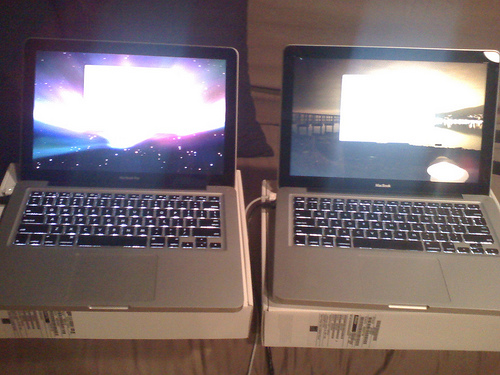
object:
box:
[260, 177, 500, 352]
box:
[0, 160, 255, 340]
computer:
[0, 35, 246, 314]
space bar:
[349, 236, 424, 251]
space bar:
[73, 232, 150, 249]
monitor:
[289, 55, 490, 183]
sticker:
[301, 312, 383, 350]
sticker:
[1, 308, 80, 338]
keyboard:
[292, 195, 499, 257]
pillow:
[0, 0, 274, 160]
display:
[29, 52, 226, 174]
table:
[0, 92, 499, 374]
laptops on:
[3, 252, 238, 304]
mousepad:
[74, 249, 159, 300]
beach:
[289, 139, 481, 184]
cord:
[245, 301, 260, 373]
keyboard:
[11, 190, 227, 252]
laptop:
[271, 42, 498, 315]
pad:
[377, 250, 452, 305]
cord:
[243, 191, 277, 217]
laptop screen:
[31, 50, 229, 175]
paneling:
[131, 340, 203, 373]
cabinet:
[0, 348, 499, 374]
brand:
[374, 181, 391, 188]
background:
[0, 0, 499, 187]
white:
[344, 76, 430, 125]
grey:
[317, 143, 386, 169]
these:
[268, 44, 499, 309]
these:
[2, 37, 243, 308]